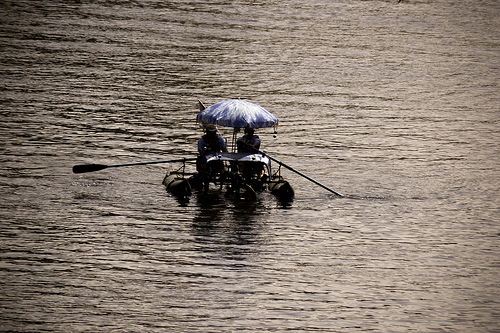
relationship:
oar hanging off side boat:
[256, 147, 343, 188] [163, 123, 296, 206]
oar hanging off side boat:
[69, 150, 195, 185] [163, 123, 296, 206]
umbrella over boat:
[199, 101, 283, 131] [163, 123, 296, 206]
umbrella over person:
[199, 101, 283, 131] [194, 125, 230, 160]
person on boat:
[194, 125, 230, 160] [163, 123, 296, 206]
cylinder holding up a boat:
[265, 174, 296, 197] [163, 123, 296, 206]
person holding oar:
[236, 127, 263, 155] [256, 147, 343, 188]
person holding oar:
[196, 125, 231, 164] [69, 150, 195, 185]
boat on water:
[163, 123, 296, 206] [1, 2, 499, 332]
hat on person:
[201, 123, 223, 130] [196, 125, 231, 164]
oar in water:
[256, 147, 343, 188] [1, 2, 499, 332]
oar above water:
[69, 150, 195, 185] [1, 2, 499, 332]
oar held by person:
[256, 147, 343, 188] [236, 127, 263, 155]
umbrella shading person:
[199, 101, 283, 131] [194, 125, 230, 160]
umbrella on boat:
[199, 101, 283, 131] [163, 123, 296, 206]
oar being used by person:
[256, 147, 343, 188] [236, 127, 263, 155]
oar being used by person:
[69, 150, 195, 185] [196, 125, 231, 164]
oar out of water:
[69, 150, 195, 185] [1, 2, 499, 332]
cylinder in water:
[265, 174, 296, 197] [1, 2, 499, 332]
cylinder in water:
[159, 168, 191, 191] [1, 2, 499, 332]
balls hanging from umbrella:
[270, 122, 283, 142] [199, 101, 283, 131]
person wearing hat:
[196, 125, 231, 164] [201, 123, 223, 130]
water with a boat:
[1, 2, 499, 332] [163, 123, 296, 206]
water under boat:
[1, 2, 499, 332] [163, 123, 296, 206]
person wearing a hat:
[196, 125, 231, 164] [201, 123, 223, 130]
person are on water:
[194, 125, 230, 160] [1, 2, 499, 332]